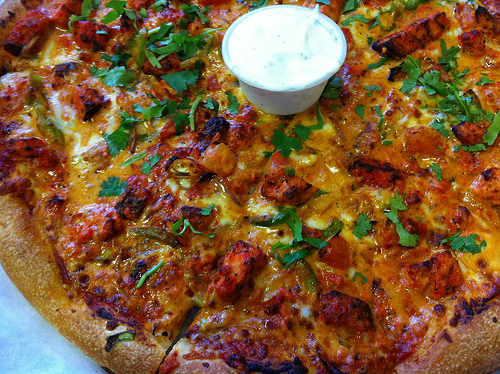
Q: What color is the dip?
A: White.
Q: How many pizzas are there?
A: One.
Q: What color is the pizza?
A: Brown, yellow, and green.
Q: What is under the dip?
A: The pizza.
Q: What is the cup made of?
A: Plastic.